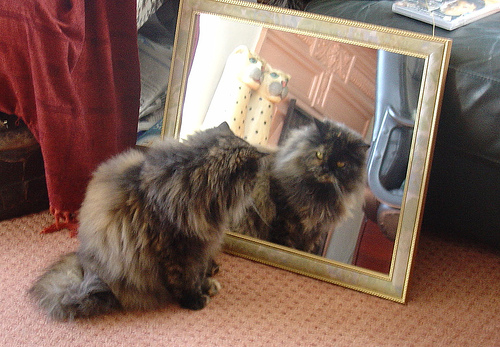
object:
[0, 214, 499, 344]
floor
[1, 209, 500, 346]
carpet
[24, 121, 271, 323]
cat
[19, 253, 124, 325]
tail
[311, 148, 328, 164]
eye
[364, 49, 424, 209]
chair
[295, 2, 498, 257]
couch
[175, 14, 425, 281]
mirror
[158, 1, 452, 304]
frame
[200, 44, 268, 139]
statue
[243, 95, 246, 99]
polka dot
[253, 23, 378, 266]
mantle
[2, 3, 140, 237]
curtain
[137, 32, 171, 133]
newspaper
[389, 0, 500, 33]
picture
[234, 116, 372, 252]
reflection